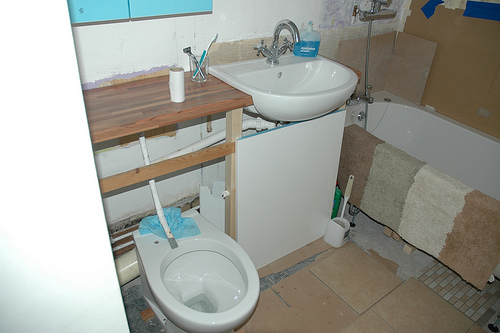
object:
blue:
[173, 219, 188, 230]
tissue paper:
[137, 209, 199, 238]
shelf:
[80, 57, 256, 148]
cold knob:
[277, 37, 293, 56]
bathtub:
[346, 94, 500, 286]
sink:
[210, 52, 360, 116]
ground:
[358, 163, 402, 208]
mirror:
[70, 0, 213, 27]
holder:
[325, 215, 350, 248]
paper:
[166, 68, 187, 105]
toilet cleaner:
[325, 186, 344, 219]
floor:
[232, 235, 496, 333]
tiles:
[307, 245, 406, 314]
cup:
[189, 56, 207, 83]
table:
[80, 65, 252, 245]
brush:
[192, 29, 224, 81]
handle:
[247, 42, 275, 65]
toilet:
[127, 213, 261, 331]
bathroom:
[0, 2, 498, 333]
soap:
[293, 19, 320, 60]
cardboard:
[397, 0, 500, 147]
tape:
[417, 2, 442, 18]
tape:
[458, 1, 498, 18]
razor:
[179, 46, 204, 82]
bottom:
[70, 11, 213, 28]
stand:
[83, 64, 243, 245]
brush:
[328, 174, 356, 234]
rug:
[336, 122, 500, 291]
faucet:
[260, 18, 303, 67]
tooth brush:
[189, 30, 222, 77]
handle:
[278, 38, 299, 55]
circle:
[236, 58, 348, 96]